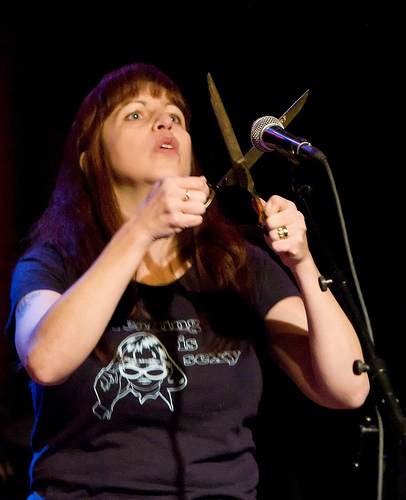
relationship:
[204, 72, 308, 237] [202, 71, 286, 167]
scissors have blades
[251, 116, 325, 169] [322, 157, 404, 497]
microphone and stand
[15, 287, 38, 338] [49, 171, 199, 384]
tatto on arm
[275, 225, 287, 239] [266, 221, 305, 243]
ring on her finger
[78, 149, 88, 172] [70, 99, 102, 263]
ear covered by hair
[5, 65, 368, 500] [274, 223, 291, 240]
girl wearing ring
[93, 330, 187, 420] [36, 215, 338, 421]
girl on a shirt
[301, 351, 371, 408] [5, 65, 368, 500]
elbow of a girl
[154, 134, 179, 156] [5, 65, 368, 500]
lips of a girl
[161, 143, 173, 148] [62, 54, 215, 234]
teeth of a woman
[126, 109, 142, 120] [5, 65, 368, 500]
eye of a girl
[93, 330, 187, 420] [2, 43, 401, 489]
girl on girls girl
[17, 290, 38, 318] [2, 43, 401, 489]
tatto on girl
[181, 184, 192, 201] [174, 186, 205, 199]
ring on finger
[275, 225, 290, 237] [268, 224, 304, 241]
rings on ring finger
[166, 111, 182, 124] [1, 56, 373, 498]
eye of girl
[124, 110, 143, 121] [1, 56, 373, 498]
eye of girl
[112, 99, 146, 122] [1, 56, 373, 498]
eyebrows of girl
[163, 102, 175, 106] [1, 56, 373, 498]
eyebrows of girl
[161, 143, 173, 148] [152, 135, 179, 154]
teeth in ladys mouth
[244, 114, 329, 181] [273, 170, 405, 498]
microphone on stand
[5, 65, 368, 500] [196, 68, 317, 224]
girl holding up scissors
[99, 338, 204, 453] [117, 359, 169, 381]
girl wearing glasses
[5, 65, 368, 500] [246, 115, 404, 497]
girl speaking into microphone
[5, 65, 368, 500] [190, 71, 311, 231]
girl holding up scissors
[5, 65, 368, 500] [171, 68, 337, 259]
girl holding up scissors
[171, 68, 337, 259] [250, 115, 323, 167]
scissors in front of microphone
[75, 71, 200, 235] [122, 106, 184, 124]
light reflecting off eyes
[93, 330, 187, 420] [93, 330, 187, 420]
girl of girl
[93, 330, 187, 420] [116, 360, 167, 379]
girl wearing glasses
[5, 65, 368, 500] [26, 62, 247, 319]
girl has hair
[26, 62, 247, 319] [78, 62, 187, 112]
hair with bangs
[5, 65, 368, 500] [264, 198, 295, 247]
girl wearing rings